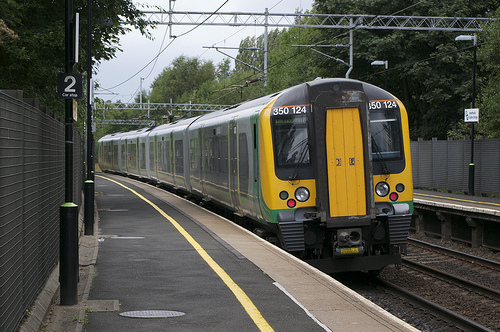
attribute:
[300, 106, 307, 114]
number 4 — white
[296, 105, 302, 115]
number — white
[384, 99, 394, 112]
number 2 — white